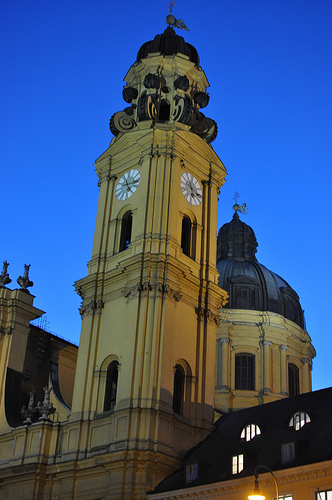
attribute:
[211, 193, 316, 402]
tower — domed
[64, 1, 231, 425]
tower — larger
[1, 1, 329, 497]
building — classical, big, stone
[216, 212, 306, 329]
roof — domed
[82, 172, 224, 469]
building — yellow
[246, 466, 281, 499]
light — yellow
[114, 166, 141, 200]
clock — gray, white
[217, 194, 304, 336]
glass — extensive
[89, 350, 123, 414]
window — arched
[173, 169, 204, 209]
clock — large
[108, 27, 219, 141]
roof — domed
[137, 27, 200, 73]
roof — black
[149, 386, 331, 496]
roof — black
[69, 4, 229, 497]
tower — large